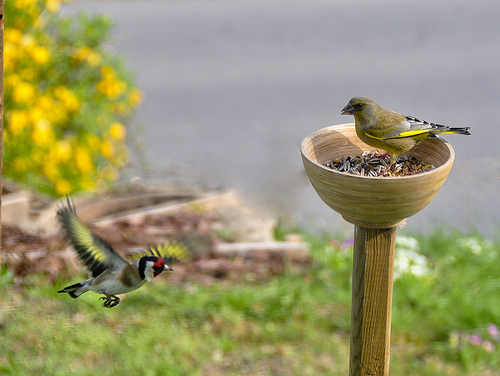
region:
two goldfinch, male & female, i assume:
[43, 79, 475, 337]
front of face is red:
[149, 251, 181, 280]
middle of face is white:
[139, 259, 159, 283]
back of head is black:
[132, 251, 158, 289]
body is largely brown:
[44, 249, 184, 322]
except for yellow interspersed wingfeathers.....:
[62, 204, 201, 282]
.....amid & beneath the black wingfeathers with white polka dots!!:
[43, 173, 223, 298]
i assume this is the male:
[16, 176, 221, 319]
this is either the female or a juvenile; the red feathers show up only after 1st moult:
[326, 82, 481, 177]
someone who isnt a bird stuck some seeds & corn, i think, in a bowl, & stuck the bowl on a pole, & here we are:
[312, 147, 444, 187]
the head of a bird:
[330, 88, 381, 135]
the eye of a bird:
[353, 94, 375, 116]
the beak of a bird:
[332, 93, 358, 126]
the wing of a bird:
[358, 111, 425, 162]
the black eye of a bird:
[348, 92, 370, 134]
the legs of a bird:
[373, 146, 421, 171]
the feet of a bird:
[371, 145, 420, 179]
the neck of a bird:
[345, 88, 400, 138]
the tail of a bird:
[407, 100, 491, 150]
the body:
[352, 54, 460, 161]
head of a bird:
[325, 84, 370, 119]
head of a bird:
[142, 235, 199, 287]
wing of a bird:
[43, 195, 115, 278]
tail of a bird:
[63, 275, 113, 310]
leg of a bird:
[93, 285, 136, 315]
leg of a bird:
[380, 154, 415, 169]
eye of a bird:
[145, 259, 160, 275]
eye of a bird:
[350, 104, 367, 113]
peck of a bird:
[162, 262, 177, 284]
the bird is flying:
[40, 185, 177, 337]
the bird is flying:
[49, 190, 189, 346]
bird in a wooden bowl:
[272, 67, 462, 240]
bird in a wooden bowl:
[274, 67, 476, 255]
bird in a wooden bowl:
[283, 62, 471, 264]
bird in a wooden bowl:
[277, 67, 482, 265]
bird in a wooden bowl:
[278, 67, 462, 263]